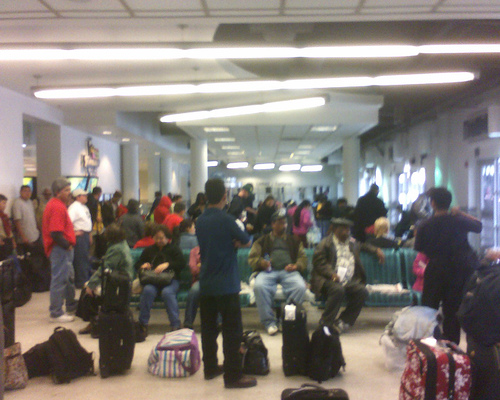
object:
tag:
[283, 305, 297, 324]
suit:
[194, 207, 247, 382]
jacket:
[308, 231, 380, 298]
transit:
[0, 121, 499, 400]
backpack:
[143, 329, 203, 376]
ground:
[341, 318, 384, 398]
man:
[192, 170, 254, 390]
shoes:
[224, 374, 257, 388]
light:
[33, 58, 474, 101]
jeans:
[47, 241, 77, 318]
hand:
[57, 245, 67, 252]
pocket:
[56, 243, 70, 260]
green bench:
[359, 246, 408, 306]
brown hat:
[330, 216, 354, 228]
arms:
[229, 220, 251, 247]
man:
[44, 176, 81, 322]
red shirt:
[39, 197, 76, 257]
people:
[183, 245, 200, 327]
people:
[132, 226, 185, 333]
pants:
[190, 283, 248, 383]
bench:
[126, 247, 461, 298]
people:
[0, 192, 17, 346]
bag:
[2, 353, 32, 391]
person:
[66, 188, 97, 290]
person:
[412, 187, 484, 347]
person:
[12, 182, 39, 269]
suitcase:
[396, 332, 486, 399]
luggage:
[308, 321, 346, 383]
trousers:
[318, 280, 363, 332]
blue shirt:
[195, 207, 248, 293]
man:
[248, 203, 308, 335]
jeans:
[253, 267, 312, 328]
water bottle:
[262, 254, 270, 272]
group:
[45, 174, 383, 351]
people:
[79, 224, 130, 334]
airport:
[2, 0, 499, 399]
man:
[311, 216, 386, 334]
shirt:
[328, 236, 358, 286]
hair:
[203, 178, 227, 208]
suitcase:
[282, 297, 311, 377]